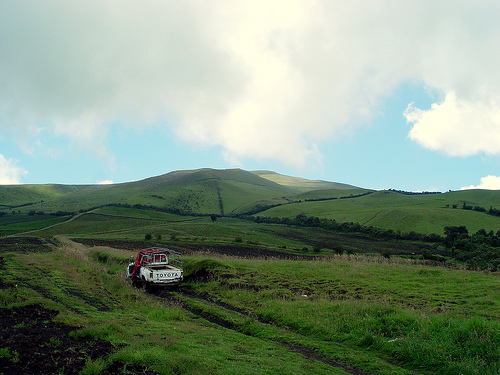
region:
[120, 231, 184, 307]
truck in a green field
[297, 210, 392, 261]
trees in a green field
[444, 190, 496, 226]
trees in a green field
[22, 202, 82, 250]
roads in a green field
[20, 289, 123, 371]
tree in a green field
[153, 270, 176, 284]
Toyota truck in green field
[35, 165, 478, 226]
mountain range in a green field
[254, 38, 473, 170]
puffy clouds in the sky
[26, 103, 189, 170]
blue sky peeking through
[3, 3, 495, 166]
thick white clouds in the blue sky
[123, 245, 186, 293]
a white Toyota truck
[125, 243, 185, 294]
a white truck parked in a field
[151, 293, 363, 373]
tire tracks on the ground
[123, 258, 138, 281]
an opened door on the driver's side of the Toyota truck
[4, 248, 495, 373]
an old white Toyota truck in a field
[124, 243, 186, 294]
a broken white Toyota truck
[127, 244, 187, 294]
a junk Toyota truck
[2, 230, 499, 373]
an abandon white truck on farmland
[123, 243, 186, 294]
an inoperable white Toyota truck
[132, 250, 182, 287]
white truck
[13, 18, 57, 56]
white clouds in blue sky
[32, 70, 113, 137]
white clouds in blue sky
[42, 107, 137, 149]
white clouds in blue sky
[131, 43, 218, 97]
white clouds in blue sky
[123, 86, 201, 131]
white clouds in blue sky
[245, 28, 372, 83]
white clouds in blue sky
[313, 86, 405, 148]
white clouds in blue sky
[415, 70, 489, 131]
white clouds in blue sky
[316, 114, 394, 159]
white clouds in blue sky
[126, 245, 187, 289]
white pick up truck with attached equipment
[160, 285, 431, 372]
two worn paths in a green grassy field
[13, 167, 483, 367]
green farmland with hills and trees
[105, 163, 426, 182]
top of two green hills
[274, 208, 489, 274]
treed area on green farm acreage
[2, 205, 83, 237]
roadway through a green farm field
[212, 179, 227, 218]
line of green trees going up a green hill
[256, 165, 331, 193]
sunlight on the side of a green hill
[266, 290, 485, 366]
tall green grass on a farmed area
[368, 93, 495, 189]
bright white clouds in a blue sky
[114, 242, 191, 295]
A white truck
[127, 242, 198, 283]
A white truck with Toyota on tailgate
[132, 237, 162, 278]
Orange item on top of white truck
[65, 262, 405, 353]
A green open field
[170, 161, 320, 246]
A green mountain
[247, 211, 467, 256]
A green tree line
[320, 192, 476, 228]
A small hilltop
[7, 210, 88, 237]
A long dirt road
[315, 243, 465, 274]
Brown dried weeds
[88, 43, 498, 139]
Blue cloudy sky